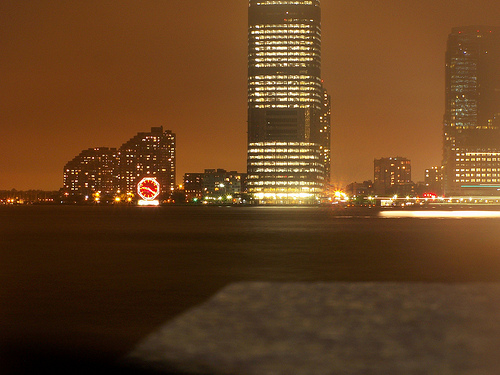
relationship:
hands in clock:
[148, 188, 157, 195] [137, 172, 162, 207]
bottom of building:
[242, 138, 327, 204] [440, 20, 498, 194]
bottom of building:
[441, 135, 498, 195] [60, 143, 120, 198]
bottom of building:
[62, 183, 137, 200] [244, 2, 334, 207]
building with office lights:
[244, 2, 334, 207] [252, 20, 302, 106]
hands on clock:
[140, 184, 157, 196] [133, 174, 163, 208]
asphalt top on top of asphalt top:
[123, 255, 497, 373] [121, 280, 498, 373]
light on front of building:
[460, 183, 498, 188] [450, 126, 498, 198]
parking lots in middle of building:
[245, 104, 308, 142] [250, 9, 337, 213]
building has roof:
[63, 120, 175, 205] [80, 120, 172, 152]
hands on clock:
[135, 171, 160, 198] [134, 169, 159, 197]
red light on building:
[488, 30, 495, 33] [440, 20, 498, 194]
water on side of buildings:
[23, 207, 495, 285] [8, 17, 498, 207]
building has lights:
[244, 2, 334, 207] [258, 27, 308, 102]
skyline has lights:
[1, 0, 498, 220] [57, 9, 485, 210]